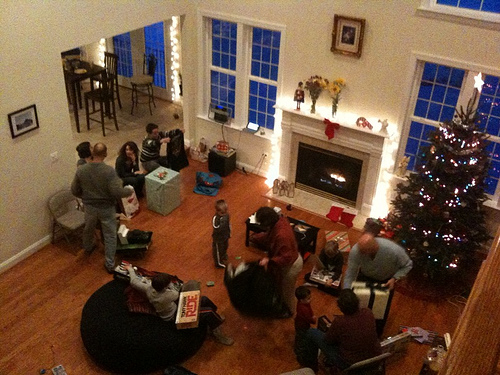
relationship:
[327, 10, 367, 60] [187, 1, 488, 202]
picture on wall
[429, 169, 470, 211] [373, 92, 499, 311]
lights on christmas tree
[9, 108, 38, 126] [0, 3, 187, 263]
picture on wall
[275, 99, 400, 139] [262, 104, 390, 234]
mantle on fire place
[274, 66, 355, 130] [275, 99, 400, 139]
flowers on mantle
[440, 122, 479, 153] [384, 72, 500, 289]
lights on christmas tree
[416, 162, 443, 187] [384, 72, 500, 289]
lights on christmas tree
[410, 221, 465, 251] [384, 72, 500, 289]
lights on christmas tree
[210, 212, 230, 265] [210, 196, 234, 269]
pajamas on toddler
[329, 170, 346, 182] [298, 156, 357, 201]
fire in fireplace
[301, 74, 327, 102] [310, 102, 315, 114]
flowers in vase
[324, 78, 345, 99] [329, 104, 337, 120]
flowers in vase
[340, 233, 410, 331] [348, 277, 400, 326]
man holding present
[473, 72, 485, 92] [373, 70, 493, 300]
star on tree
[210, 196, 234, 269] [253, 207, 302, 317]
toddler watching woman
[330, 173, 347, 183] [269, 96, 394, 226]
fire in fireplace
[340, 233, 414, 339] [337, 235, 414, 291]
man wearing gray sweater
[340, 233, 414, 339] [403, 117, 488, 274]
man holding present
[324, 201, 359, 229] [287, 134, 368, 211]
stockings by fireplace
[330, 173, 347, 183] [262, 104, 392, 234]
fire in fire place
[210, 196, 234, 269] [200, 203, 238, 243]
toddler in sweatshirt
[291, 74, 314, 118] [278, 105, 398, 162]
nutcracker on mantle